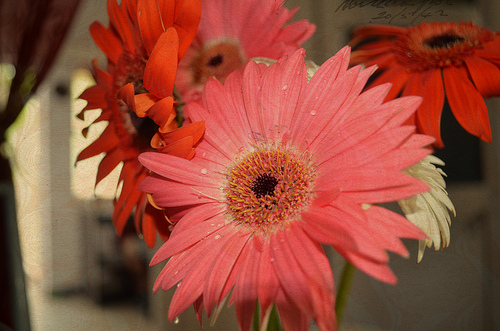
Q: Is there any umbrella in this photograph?
A: No, there are no umbrellas.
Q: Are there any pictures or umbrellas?
A: No, there are no umbrellas or pictures.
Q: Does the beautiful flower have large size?
A: Yes, the flower is large.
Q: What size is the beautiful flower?
A: The flower is large.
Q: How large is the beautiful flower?
A: The flower is large.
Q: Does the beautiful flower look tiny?
A: No, the flower is large.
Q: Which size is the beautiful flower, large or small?
A: The flower is large.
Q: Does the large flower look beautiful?
A: Yes, the flower is beautiful.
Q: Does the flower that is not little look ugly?
A: No, the flower is beautiful.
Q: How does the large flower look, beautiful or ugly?
A: The flower is beautiful.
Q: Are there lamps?
A: No, there are no lamps.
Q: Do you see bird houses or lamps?
A: No, there are no lamps or bird houses.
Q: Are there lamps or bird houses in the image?
A: No, there are no lamps or bird houses.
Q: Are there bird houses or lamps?
A: No, there are no lamps or bird houses.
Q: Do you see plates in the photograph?
A: No, there are no plates.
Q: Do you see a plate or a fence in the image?
A: No, there are no plates or fences.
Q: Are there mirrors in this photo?
A: No, there are no mirrors.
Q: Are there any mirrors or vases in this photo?
A: No, there are no mirrors or vases.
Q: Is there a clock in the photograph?
A: No, there are no clocks.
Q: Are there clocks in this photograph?
A: No, there are no clocks.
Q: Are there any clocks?
A: No, there are no clocks.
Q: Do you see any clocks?
A: No, there are no clocks.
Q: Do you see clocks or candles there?
A: No, there are no clocks or candles.